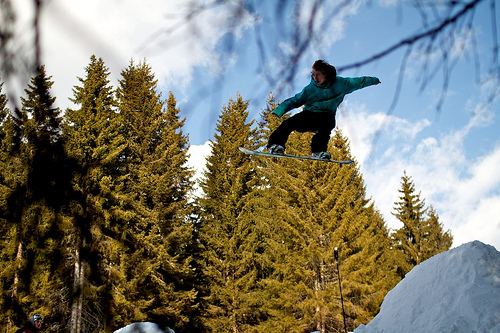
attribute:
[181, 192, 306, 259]
leaves — green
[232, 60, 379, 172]
snowboarder — high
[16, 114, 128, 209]
shadow — dark, lines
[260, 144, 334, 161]
shoes — some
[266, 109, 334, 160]
knees — bent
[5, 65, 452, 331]
forest — thick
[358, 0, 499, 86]
branch — leafless, hanging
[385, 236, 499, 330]
mountain — snow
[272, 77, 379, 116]
jacket — teal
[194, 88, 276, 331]
tree — pine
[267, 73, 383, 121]
coat — green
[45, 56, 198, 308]
trees — pine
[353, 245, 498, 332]
snow — piled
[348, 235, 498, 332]
snow hill — on right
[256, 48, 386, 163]
person — hatless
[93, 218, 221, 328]
trees — yellowish-green, row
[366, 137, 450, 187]
clouds — white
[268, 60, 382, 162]
man — snowboarding, in mid air